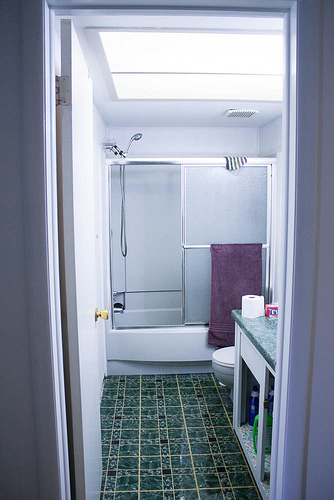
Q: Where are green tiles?
A: On the floor.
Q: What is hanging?
A: A purple towel.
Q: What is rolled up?
A: Toilet paper.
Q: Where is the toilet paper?
A: On countertop.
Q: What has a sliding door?
A: The bathtub.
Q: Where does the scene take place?
A: In a bathroom.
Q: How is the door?
A: Wide open.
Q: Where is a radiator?
A: On shower ceiling.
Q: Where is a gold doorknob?
A: On the door.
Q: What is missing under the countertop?
A: Cabinet doors.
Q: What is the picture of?
A: A bathroom.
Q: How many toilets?
A: One.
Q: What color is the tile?
A: Green and gold.